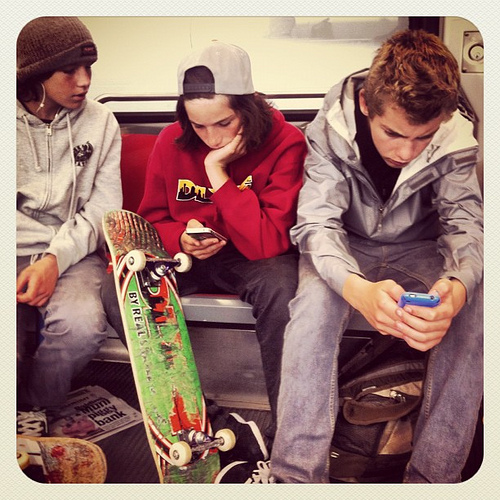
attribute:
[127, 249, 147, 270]
wheel — White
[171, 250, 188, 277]
wheel — White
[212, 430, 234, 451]
wheel — White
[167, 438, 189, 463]
wheel — White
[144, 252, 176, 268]
truck — silver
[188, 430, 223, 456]
truck — silver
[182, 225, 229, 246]
smartphone — silver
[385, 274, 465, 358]
phone — blue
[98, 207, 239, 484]
skateboard — green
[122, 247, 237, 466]
wheels — white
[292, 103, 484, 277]
jacket — grey